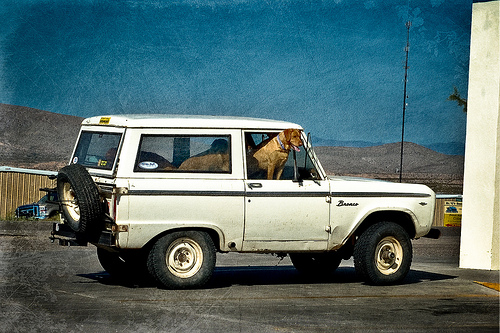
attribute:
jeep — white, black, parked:
[56, 113, 441, 293]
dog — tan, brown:
[249, 130, 303, 181]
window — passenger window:
[244, 130, 323, 182]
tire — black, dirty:
[145, 232, 218, 291]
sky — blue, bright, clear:
[1, 1, 473, 158]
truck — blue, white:
[12, 192, 61, 219]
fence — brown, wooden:
[0, 169, 58, 219]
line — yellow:
[121, 290, 492, 304]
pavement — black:
[1, 229, 496, 333]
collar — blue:
[273, 134, 288, 153]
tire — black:
[357, 219, 414, 286]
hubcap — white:
[165, 238, 203, 278]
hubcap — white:
[375, 238, 405, 276]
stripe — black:
[118, 190, 435, 201]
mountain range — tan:
[0, 99, 464, 195]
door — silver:
[248, 181, 263, 191]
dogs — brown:
[104, 114, 304, 185]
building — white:
[449, 0, 499, 270]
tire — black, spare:
[55, 165, 104, 243]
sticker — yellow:
[97, 115, 113, 125]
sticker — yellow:
[99, 157, 109, 167]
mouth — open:
[291, 143, 306, 153]